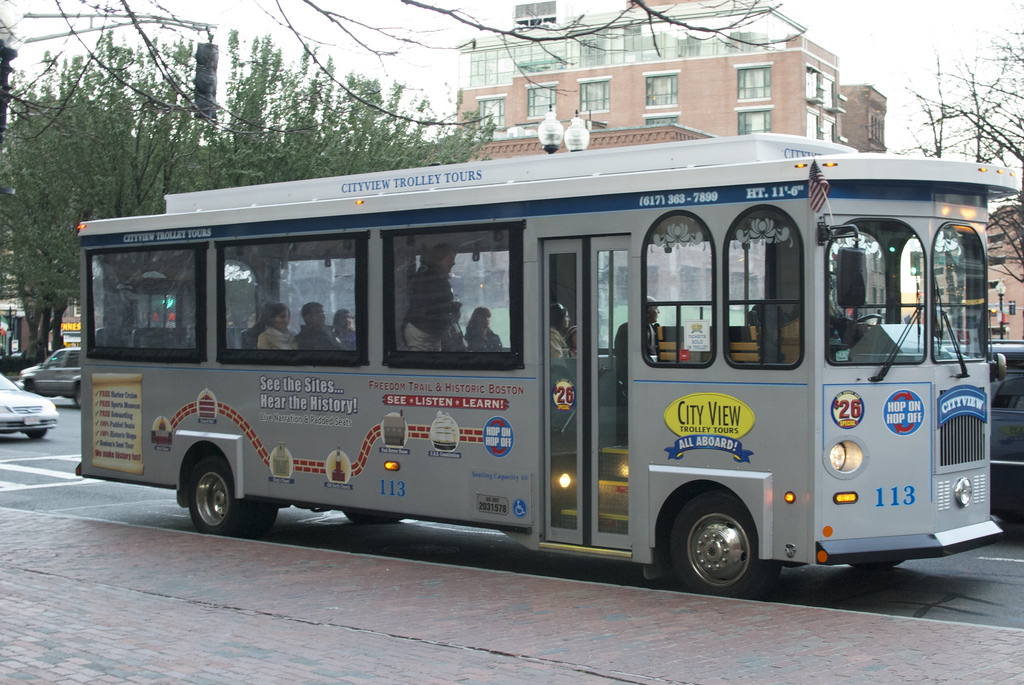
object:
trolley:
[74, 103, 1021, 600]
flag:
[808, 159, 832, 214]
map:
[150, 383, 514, 490]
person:
[403, 243, 463, 352]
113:
[876, 485, 915, 506]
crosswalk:
[0, 454, 107, 494]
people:
[257, 304, 300, 351]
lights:
[559, 472, 572, 488]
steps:
[561, 446, 629, 536]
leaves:
[41, 50, 58, 67]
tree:
[0, 30, 496, 360]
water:
[663, 434, 753, 464]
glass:
[392, 229, 512, 352]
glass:
[729, 209, 801, 364]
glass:
[646, 215, 712, 364]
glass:
[224, 239, 356, 350]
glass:
[91, 250, 197, 349]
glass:
[830, 221, 926, 363]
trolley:
[392, 174, 439, 188]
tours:
[444, 170, 482, 183]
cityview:
[342, 180, 391, 193]